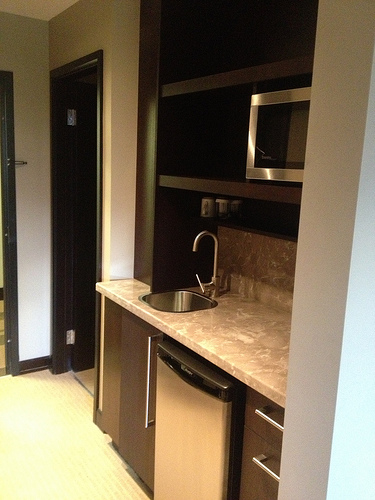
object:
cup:
[200, 195, 218, 218]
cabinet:
[116, 308, 161, 496]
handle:
[255, 405, 285, 435]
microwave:
[242, 81, 314, 186]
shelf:
[159, 55, 310, 102]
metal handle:
[143, 332, 159, 429]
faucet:
[192, 230, 221, 300]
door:
[48, 46, 102, 396]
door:
[116, 307, 165, 492]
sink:
[138, 289, 219, 314]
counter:
[94, 275, 289, 403]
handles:
[250, 452, 279, 483]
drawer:
[242, 385, 285, 455]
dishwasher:
[152, 339, 248, 499]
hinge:
[66, 328, 76, 347]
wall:
[0, 9, 45, 370]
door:
[0, 71, 23, 375]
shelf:
[191, 206, 295, 241]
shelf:
[157, 170, 304, 208]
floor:
[0, 363, 154, 498]